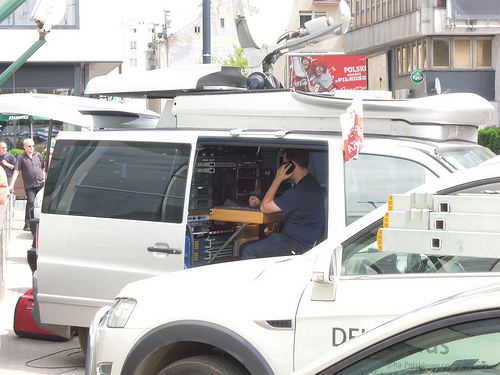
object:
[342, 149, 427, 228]
window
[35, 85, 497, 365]
vehicle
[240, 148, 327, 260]
man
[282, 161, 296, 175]
phone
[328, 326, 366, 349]
de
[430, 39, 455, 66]
window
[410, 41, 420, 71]
window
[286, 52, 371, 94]
poster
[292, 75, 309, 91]
cola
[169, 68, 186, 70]
isaldn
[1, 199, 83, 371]
road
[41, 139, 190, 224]
window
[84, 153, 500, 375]
vehicle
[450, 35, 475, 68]
window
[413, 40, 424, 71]
glass window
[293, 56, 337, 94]
clown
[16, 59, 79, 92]
window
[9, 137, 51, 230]
man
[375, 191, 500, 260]
ladder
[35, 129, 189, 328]
door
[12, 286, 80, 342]
bag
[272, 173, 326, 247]
black outfit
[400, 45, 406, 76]
window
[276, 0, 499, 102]
building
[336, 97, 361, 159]
poster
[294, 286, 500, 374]
vehicle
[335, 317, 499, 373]
window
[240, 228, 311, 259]
pants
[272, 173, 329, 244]
shirt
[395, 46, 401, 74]
window